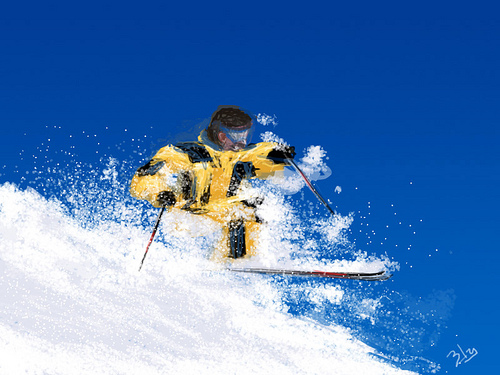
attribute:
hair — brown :
[208, 102, 252, 146]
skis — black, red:
[228, 258, 385, 279]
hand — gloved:
[152, 186, 187, 208]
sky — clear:
[308, 49, 445, 184]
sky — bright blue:
[3, 2, 498, 147]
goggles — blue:
[224, 126, 266, 141]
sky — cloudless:
[0, 1, 499, 374]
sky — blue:
[4, 3, 472, 100]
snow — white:
[48, 299, 118, 374]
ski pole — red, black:
[282, 147, 339, 219]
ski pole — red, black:
[132, 200, 167, 270]